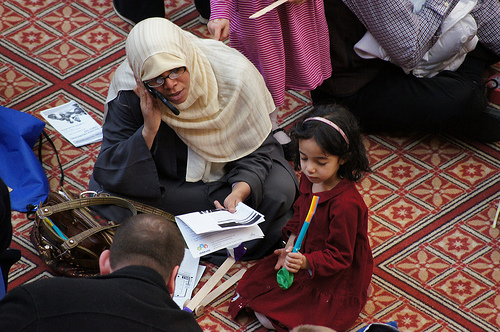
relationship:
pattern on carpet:
[411, 174, 464, 214] [0, 0, 500, 329]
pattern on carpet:
[7, 7, 497, 331] [0, 0, 500, 329]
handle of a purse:
[45, 184, 142, 257] [13, 173, 165, 292]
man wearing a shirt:
[0, 213, 202, 332] [7, 262, 194, 330]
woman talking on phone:
[88, 16, 297, 231] [144, 80, 189, 132]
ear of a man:
[167, 262, 179, 296] [0, 213, 202, 332]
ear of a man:
[92, 250, 123, 282] [0, 213, 202, 332]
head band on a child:
[301, 113, 350, 141] [223, 106, 376, 330]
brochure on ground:
[38, 100, 106, 148] [1, 0, 498, 330]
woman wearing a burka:
[88, 16, 298, 265] [85, 78, 301, 232]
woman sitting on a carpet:
[88, 16, 298, 265] [0, 0, 500, 332]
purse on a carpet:
[36, 164, 144, 290] [0, 0, 500, 332]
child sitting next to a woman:
[229, 117, 372, 332] [72, 13, 234, 139]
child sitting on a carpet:
[229, 117, 372, 332] [0, 0, 500, 332]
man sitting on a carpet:
[330, 0, 498, 140] [0, 0, 500, 332]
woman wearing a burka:
[88, 16, 297, 231] [113, 10, 270, 150]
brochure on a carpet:
[38, 100, 106, 148] [0, 0, 500, 332]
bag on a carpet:
[3, 111, 58, 208] [0, 0, 500, 332]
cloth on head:
[126, 27, 316, 162] [124, 30, 208, 98]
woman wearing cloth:
[88, 16, 298, 265] [126, 27, 316, 162]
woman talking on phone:
[88, 16, 298, 265] [138, 81, 186, 121]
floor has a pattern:
[3, 3, 495, 323] [7, 7, 497, 331]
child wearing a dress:
[229, 117, 372, 332] [230, 177, 373, 325]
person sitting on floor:
[85, 17, 299, 261] [3, 3, 495, 323]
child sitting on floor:
[229, 117, 372, 332] [3, 3, 495, 323]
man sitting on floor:
[0, 213, 202, 332] [3, 3, 495, 323]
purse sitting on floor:
[27, 189, 139, 280] [3, 3, 495, 323]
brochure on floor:
[31, 79, 103, 134] [393, 189, 451, 232]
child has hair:
[229, 117, 372, 332] [287, 105, 367, 180]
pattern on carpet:
[371, 151, 487, 330] [410, 207, 481, 302]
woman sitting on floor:
[88, 16, 298, 265] [379, 172, 482, 305]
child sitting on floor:
[229, 117, 372, 327] [379, 172, 482, 305]